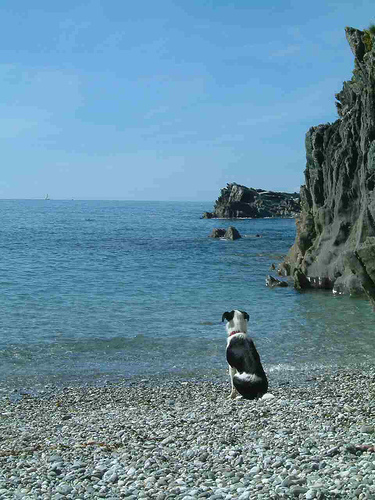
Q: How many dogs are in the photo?
A: One.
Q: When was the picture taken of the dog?
A: Daytime.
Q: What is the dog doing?
A: Sitting.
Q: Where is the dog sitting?
A: On the rocks.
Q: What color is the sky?
A: Blue.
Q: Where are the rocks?
A: On the ground.